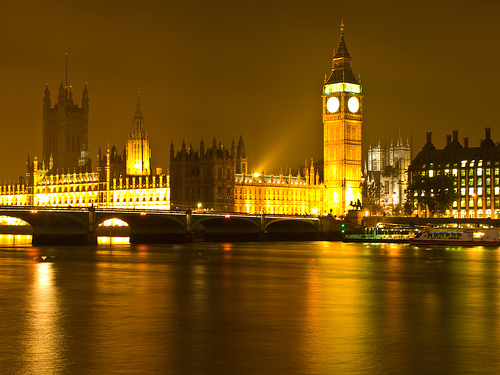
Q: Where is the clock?
A: On the building.